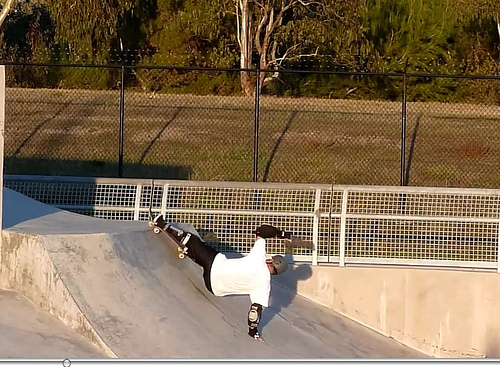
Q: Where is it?
A: This is at the park.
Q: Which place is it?
A: It is a park.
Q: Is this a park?
A: Yes, it is a park.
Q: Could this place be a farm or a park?
A: It is a park.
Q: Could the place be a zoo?
A: No, it is a park.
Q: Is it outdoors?
A: Yes, it is outdoors.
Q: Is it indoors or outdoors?
A: It is outdoors.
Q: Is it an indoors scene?
A: No, it is outdoors.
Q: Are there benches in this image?
A: No, there are no benches.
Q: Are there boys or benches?
A: No, there are no benches or boys.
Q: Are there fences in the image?
A: Yes, there is a fence.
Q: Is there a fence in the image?
A: Yes, there is a fence.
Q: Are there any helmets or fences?
A: Yes, there is a fence.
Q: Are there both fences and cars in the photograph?
A: No, there is a fence but no cars.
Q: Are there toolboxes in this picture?
A: No, there are no toolboxes.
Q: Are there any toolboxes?
A: No, there are no toolboxes.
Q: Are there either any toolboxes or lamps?
A: No, there are no toolboxes or lamps.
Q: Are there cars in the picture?
A: No, there are no cars.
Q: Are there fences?
A: Yes, there is a fence.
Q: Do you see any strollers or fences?
A: Yes, there is a fence.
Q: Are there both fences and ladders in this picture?
A: No, there is a fence but no ladders.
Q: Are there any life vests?
A: No, there are no life vests.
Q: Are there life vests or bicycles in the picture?
A: No, there are no life vests or bicycles.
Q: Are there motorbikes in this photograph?
A: No, there are no motorbikes.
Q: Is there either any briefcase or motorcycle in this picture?
A: No, there are no motorcycles or briefcases.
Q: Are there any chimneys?
A: No, there are no chimneys.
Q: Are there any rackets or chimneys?
A: No, there are no chimneys or rackets.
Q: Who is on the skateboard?
A: The man is on the skateboard.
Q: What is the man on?
A: The man is on the skateboard.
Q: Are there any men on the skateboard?
A: Yes, there is a man on the skateboard.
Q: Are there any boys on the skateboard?
A: No, there is a man on the skateboard.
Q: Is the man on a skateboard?
A: Yes, the man is on a skateboard.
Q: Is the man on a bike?
A: No, the man is on a skateboard.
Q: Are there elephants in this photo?
A: No, there are no elephants.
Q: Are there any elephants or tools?
A: No, there are no elephants or tools.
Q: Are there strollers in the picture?
A: No, there are no strollers.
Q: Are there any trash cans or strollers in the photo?
A: No, there are no strollers or trash cans.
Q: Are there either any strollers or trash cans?
A: No, there are no strollers or trash cans.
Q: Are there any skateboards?
A: Yes, there is a skateboard.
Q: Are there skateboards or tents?
A: Yes, there is a skateboard.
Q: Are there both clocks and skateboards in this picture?
A: No, there is a skateboard but no clocks.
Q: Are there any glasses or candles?
A: No, there are no glasses or candles.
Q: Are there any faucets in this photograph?
A: No, there are no faucets.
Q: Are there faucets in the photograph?
A: No, there are no faucets.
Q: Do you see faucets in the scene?
A: No, there are no faucets.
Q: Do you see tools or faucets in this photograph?
A: No, there are no faucets or tools.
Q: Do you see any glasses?
A: No, there are no glasses.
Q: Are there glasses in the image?
A: No, there are no glasses.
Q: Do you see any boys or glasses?
A: No, there are no glasses or boys.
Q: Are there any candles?
A: No, there are no candles.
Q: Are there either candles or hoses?
A: No, there are no candles or hoses.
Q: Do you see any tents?
A: No, there are no tents.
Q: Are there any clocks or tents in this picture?
A: No, there are no tents or clocks.